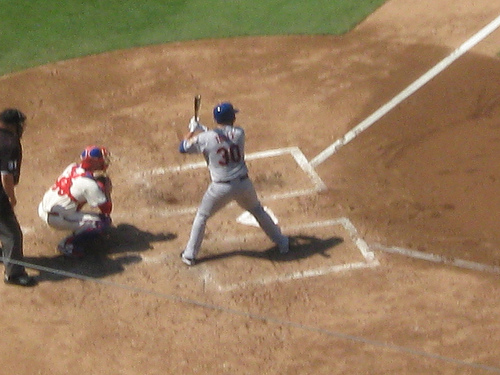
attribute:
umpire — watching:
[3, 100, 35, 294]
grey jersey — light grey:
[178, 122, 262, 175]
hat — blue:
[208, 96, 242, 125]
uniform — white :
[31, 123, 115, 261]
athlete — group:
[176, 95, 278, 280]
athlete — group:
[45, 135, 120, 260]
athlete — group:
[6, 93, 36, 300]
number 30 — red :
[217, 146, 241, 166]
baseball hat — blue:
[211, 101, 241, 120]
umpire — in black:
[0, 106, 37, 288]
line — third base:
[312, 17, 499, 169]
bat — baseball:
[184, 91, 210, 126]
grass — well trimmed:
[1, 0, 385, 80]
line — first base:
[364, 238, 499, 275]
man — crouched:
[40, 142, 114, 255]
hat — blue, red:
[72, 139, 105, 162]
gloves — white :
[185, 114, 204, 136]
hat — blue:
[202, 103, 276, 140]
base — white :
[233, 198, 282, 237]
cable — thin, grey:
[0, 256, 499, 372]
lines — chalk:
[117, 19, 498, 295]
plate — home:
[234, 204, 280, 229]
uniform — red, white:
[34, 161, 108, 236]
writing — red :
[216, 132, 236, 144]